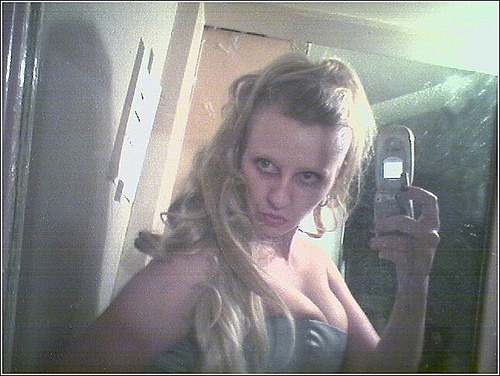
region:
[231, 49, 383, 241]
the head of a woman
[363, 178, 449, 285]
the hand of a woman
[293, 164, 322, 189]
the eye of a woman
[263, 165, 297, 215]
the nose of a woman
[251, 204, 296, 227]
the mouth of a woman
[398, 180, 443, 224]
the finger of a woman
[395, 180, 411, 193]
the finger nail of a woman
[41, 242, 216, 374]
the arm of a woman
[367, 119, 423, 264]
a gray cell phone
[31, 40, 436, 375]
a woman holding a cell phone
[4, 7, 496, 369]
a woman with a flip phone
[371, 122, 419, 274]
the cell phone is on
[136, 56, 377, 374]
the woman has long blonde hair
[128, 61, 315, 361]
the hair has loose curls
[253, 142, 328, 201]
the girl has blue eyes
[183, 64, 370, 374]
the girl is wearing a low cut dress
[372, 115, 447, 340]
the phone is in the left hand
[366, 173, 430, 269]
the girl has red nail polish on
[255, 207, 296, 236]
the woman is wearing red lipstick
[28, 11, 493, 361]
the girl is standing in a doorway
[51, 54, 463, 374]
a woman posing for a picture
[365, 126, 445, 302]
cellphone held in hand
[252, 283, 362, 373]
boobs overflowing top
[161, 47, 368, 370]
woman has long blond hair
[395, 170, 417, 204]
small antenna on phone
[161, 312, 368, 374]
a gray top on the woman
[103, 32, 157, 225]
a white paper taped to wall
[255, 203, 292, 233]
red lips of a woman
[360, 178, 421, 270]
red finger nails of woman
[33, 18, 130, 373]
shadow cast on wall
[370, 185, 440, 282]
hand is up and a finger flex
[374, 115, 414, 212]
silver cell phone with flash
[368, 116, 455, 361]
a woman holding a cell phone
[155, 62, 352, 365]
a woman with long blond hair posing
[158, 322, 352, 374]
woman wearing a green sleeveless top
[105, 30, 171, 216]
calendar on the wall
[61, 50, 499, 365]
person taking a self portrait picture from her cell phone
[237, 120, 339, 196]
woman with brown eyes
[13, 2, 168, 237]
white wall with brown trim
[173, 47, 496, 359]
opened door behind woman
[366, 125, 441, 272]
a small flip phone in a woman's hand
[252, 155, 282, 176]
right eye of a woman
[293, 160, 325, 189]
left eye of a woman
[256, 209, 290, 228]
mouth of a woman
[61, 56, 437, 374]
a blond woman taking a picture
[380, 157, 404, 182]
lcd screen on a phone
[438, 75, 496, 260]
scratches on a mirror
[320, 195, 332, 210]
a golden earring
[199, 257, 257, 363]
blond hair on a woman